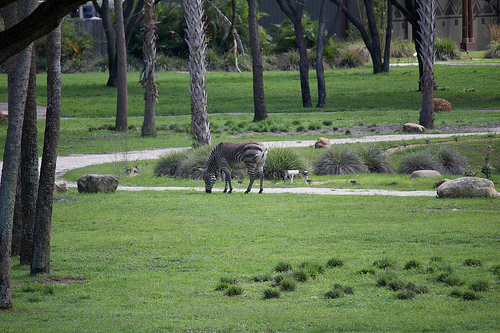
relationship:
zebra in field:
[193, 138, 268, 193] [2, 72, 499, 332]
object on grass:
[283, 165, 300, 182] [71, 135, 497, 191]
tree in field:
[406, 4, 447, 133] [2, 72, 499, 332]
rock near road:
[77, 168, 121, 195] [2, 130, 456, 191]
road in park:
[2, 130, 456, 191] [5, 60, 495, 332]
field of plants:
[2, 72, 499, 332] [136, 3, 327, 59]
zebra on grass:
[193, 138, 268, 193] [71, 135, 497, 191]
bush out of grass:
[158, 146, 215, 178] [71, 135, 497, 191]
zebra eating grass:
[193, 138, 268, 193] [71, 135, 497, 191]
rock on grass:
[77, 168, 121, 195] [71, 135, 497, 191]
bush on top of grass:
[158, 146, 215, 178] [71, 135, 497, 191]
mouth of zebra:
[203, 187, 214, 195] [193, 138, 268, 193]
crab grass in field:
[215, 246, 353, 315] [2, 72, 499, 332]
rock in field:
[77, 168, 121, 195] [2, 72, 499, 332]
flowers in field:
[104, 128, 141, 177] [2, 72, 499, 332]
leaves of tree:
[422, 33, 425, 56] [406, 4, 447, 133]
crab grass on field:
[215, 246, 353, 315] [2, 72, 499, 332]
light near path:
[409, 49, 419, 65] [68, 175, 439, 208]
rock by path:
[77, 168, 121, 195] [68, 175, 439, 208]